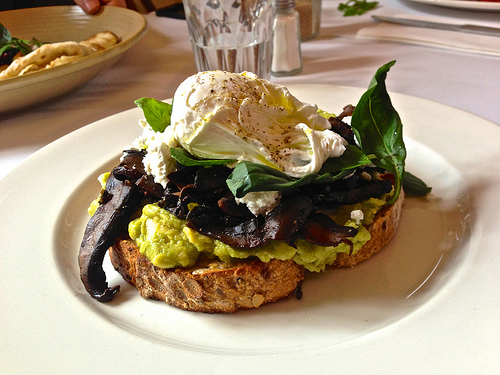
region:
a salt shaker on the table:
[267, 0, 308, 80]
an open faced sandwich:
[72, 51, 413, 313]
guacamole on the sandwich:
[128, 200, 369, 275]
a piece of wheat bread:
[110, 185, 407, 315]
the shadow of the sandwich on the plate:
[269, 170, 487, 316]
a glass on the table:
[178, 0, 278, 77]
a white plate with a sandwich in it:
[2, 68, 498, 373]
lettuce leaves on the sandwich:
[323, 55, 410, 222]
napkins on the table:
[352, 8, 498, 56]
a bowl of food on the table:
[0, 6, 151, 117]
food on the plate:
[23, 67, 448, 334]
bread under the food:
[148, 257, 291, 334]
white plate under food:
[383, 230, 471, 310]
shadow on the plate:
[428, 152, 492, 274]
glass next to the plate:
[181, 8, 292, 73]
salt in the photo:
[258, 2, 325, 69]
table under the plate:
[415, 52, 484, 104]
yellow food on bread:
[142, 205, 200, 252]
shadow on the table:
[317, 39, 363, 81]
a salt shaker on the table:
[273, 0, 308, 78]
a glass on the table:
[192, 2, 282, 76]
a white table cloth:
[47, 12, 476, 120]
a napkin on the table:
[360, 5, 486, 67]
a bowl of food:
[3, 8, 144, 85]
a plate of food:
[32, 79, 487, 338]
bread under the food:
[138, 241, 270, 282]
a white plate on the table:
[9, 78, 494, 338]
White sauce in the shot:
[146, 62, 356, 202]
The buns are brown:
[85, 136, 434, 328]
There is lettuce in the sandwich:
[51, 78, 428, 303]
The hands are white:
[61, 0, 174, 37]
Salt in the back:
[268, 5, 323, 85]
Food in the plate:
[0, 20, 144, 85]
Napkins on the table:
[361, 2, 498, 82]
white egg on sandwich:
[162, 63, 297, 153]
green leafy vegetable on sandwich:
[163, 108, 434, 166]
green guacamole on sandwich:
[108, 181, 348, 281]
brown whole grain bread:
[104, 203, 404, 305]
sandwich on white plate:
[47, 100, 464, 374]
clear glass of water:
[186, 8, 283, 95]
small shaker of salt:
[249, 8, 336, 83]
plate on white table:
[106, 62, 495, 367]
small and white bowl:
[5, 21, 119, 88]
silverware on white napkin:
[332, 19, 498, 42]